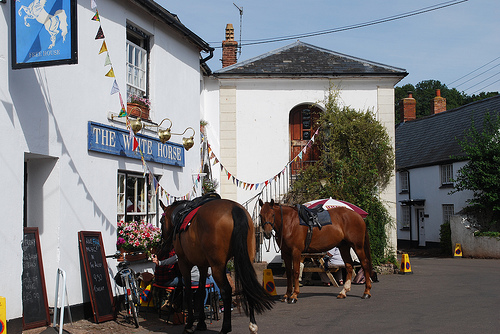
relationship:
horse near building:
[150, 190, 290, 332] [2, 1, 422, 323]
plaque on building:
[86, 117, 189, 173] [2, 1, 422, 323]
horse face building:
[247, 182, 407, 297] [2, 1, 422, 323]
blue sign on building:
[87, 117, 196, 172] [2, 1, 422, 323]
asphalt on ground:
[78, 233, 497, 332] [49, 248, 498, 332]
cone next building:
[452, 243, 463, 258] [390, 83, 498, 258]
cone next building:
[398, 253, 413, 275] [194, 21, 416, 269]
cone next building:
[398, 253, 413, 275] [0, 0, 209, 332]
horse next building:
[259, 198, 373, 303] [13, 2, 231, 315]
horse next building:
[161, 192, 288, 334] [13, 2, 231, 315]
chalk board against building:
[74, 228, 125, 323] [2, 1, 422, 323]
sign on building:
[9, 0, 79, 70] [2, 1, 422, 323]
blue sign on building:
[87, 121, 185, 167] [2, 1, 422, 323]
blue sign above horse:
[87, 121, 185, 167] [142, 189, 236, 264]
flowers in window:
[129, 92, 150, 109] [122, 38, 151, 112]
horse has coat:
[161, 192, 288, 334] [171, 187, 219, 272]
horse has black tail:
[161, 192, 288, 334] [231, 204, 275, 316]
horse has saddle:
[259, 198, 373, 303] [294, 203, 331, 225]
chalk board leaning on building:
[77, 230, 117, 322] [0, 0, 209, 332]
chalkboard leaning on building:
[21, 225, 51, 327] [0, 0, 209, 332]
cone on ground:
[397, 249, 413, 278] [25, 245, 499, 334]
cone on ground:
[0, 293, 10, 332] [25, 245, 499, 334]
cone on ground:
[261, 264, 279, 299] [25, 245, 499, 334]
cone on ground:
[449, 237, 464, 259] [25, 245, 499, 334]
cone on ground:
[398, 253, 413, 275] [25, 245, 499, 334]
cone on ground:
[452, 243, 463, 258] [25, 245, 499, 334]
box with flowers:
[119, 241, 163, 263] [114, 218, 163, 248]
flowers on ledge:
[98, 215, 173, 260] [108, 112, 159, 132]